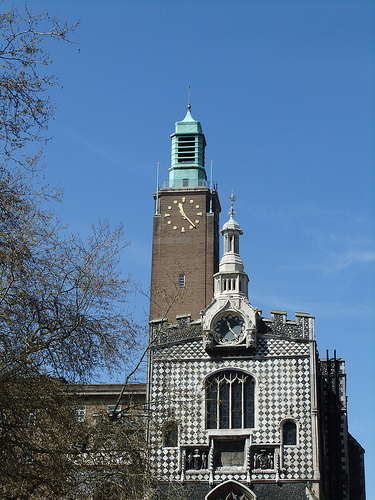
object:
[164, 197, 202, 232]
clock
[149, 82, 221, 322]
building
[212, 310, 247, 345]
clock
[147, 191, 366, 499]
building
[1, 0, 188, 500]
branches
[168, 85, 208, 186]
tower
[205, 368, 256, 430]
window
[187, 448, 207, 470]
statues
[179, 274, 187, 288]
window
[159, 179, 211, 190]
safety rail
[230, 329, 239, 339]
hand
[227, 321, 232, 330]
hand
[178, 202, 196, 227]
hands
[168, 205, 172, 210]
dots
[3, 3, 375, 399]
sky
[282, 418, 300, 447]
window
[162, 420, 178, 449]
window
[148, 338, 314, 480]
wall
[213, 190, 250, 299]
steeple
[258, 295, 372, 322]
cloud